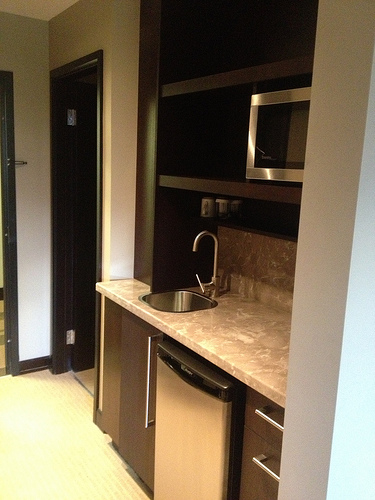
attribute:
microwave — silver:
[236, 95, 324, 194]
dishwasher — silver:
[153, 342, 231, 498]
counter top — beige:
[95, 278, 291, 409]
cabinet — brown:
[116, 308, 161, 491]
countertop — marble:
[81, 245, 280, 388]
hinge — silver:
[59, 312, 77, 350]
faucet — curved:
[179, 227, 240, 309]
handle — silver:
[244, 401, 295, 437]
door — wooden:
[106, 299, 152, 498]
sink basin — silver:
[144, 289, 214, 310]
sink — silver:
[138, 289, 219, 316]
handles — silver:
[247, 408, 282, 488]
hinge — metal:
[60, 323, 76, 350]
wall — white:
[0, 9, 45, 370]